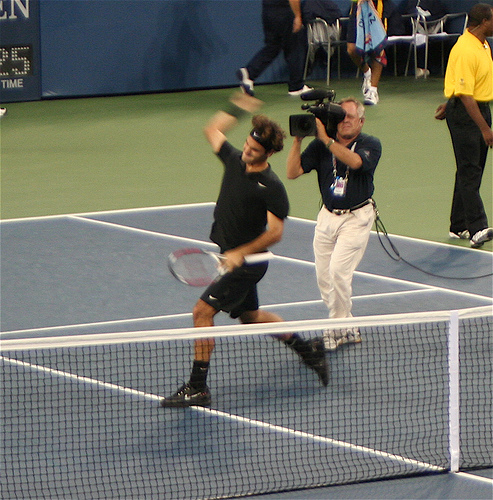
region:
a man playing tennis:
[154, 92, 331, 407]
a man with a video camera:
[283, 86, 380, 354]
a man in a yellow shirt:
[441, 2, 491, 247]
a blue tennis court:
[0, 202, 491, 497]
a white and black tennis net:
[2, 308, 489, 497]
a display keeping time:
[0, 42, 35, 92]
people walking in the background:
[238, 0, 392, 109]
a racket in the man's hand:
[168, 246, 272, 286]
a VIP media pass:
[330, 175, 346, 199]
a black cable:
[375, 204, 491, 280]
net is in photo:
[1, 300, 491, 497]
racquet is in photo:
[165, 246, 281, 287]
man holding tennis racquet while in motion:
[158, 87, 337, 427]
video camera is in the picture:
[280, 84, 347, 152]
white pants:
[311, 198, 380, 312]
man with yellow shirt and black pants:
[432, 1, 489, 247]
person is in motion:
[224, 0, 316, 98]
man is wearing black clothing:
[155, 87, 328, 418]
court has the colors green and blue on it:
[6, 102, 491, 497]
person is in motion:
[327, 0, 390, 113]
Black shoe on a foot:
[141, 354, 248, 445]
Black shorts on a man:
[194, 247, 287, 317]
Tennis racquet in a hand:
[152, 232, 318, 295]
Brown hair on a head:
[221, 108, 307, 189]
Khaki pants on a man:
[301, 195, 387, 332]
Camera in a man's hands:
[270, 70, 341, 161]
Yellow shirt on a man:
[440, 20, 491, 122]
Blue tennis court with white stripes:
[34, 196, 163, 276]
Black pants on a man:
[247, 6, 332, 89]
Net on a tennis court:
[71, 313, 393, 498]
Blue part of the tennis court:
[54, 252, 87, 287]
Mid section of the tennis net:
[158, 386, 229, 423]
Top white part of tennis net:
[172, 316, 325, 335]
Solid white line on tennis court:
[105, 219, 166, 244]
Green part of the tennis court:
[133, 106, 166, 141]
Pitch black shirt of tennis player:
[226, 174, 254, 219]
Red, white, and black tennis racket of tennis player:
[165, 245, 220, 285]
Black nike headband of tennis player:
[248, 122, 270, 150]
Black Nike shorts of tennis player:
[203, 278, 264, 308]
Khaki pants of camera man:
[317, 234, 357, 302]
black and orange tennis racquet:
[157, 242, 228, 287]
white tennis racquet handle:
[241, 247, 279, 263]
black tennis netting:
[374, 333, 442, 442]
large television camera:
[283, 85, 345, 142]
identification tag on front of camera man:
[329, 173, 350, 194]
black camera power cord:
[387, 242, 489, 283]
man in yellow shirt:
[430, 0, 491, 244]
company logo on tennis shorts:
[204, 293, 223, 302]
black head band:
[247, 128, 274, 150]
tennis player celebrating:
[128, 73, 291, 399]